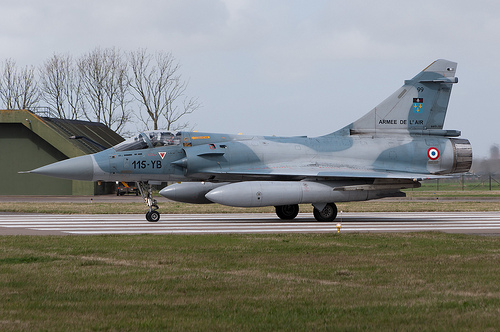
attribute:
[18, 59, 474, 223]
jet — camouflaged, blue, grey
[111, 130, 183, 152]
cockpit — glass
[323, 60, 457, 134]
tail — grey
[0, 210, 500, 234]
runway — grey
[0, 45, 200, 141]
trees — bare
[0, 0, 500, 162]
sky — overcast, grey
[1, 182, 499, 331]
grass — green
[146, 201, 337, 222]
wheels — black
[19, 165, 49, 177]
nose — grey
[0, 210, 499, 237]
lines — white